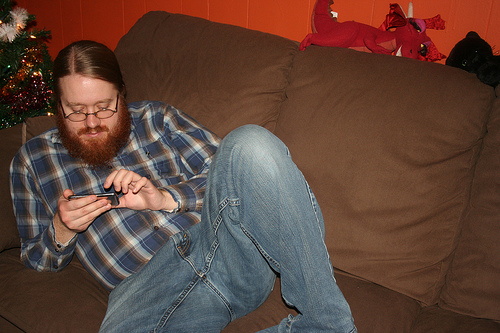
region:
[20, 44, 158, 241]
A man looking at a cell phone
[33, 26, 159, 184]
A man wearing glasses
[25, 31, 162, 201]
A man with a beard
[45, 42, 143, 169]
A man with a mustache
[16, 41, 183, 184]
A man with a beard and a mustache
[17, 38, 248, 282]
A man wearing a plaid shirt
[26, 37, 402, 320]
A man wearing blue jeans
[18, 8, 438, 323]
A man lounging on a sofa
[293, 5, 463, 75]
A stuffed red dinosaur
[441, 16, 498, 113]
A stuffed black cat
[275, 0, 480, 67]
stuffed red dragon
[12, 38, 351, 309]
man using his cellphone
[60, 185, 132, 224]
thin grey cellphone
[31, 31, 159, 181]
man with a thick orange beard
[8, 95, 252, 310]
blue white and orange checkered shirt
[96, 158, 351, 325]
faded blue jeans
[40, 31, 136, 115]
orange hair that is slicked down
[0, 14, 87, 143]
christmas tree with decorations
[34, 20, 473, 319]
man sitting on a brown couch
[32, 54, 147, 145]
man wearing glasses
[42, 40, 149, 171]
Male wearing glasses with a large red beard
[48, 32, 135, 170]
Slicked red hair on a male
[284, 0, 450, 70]
Red stuffed dragon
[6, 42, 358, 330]
Man laying on couch looking at phone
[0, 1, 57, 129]
Decorated Christmas tree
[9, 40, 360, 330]
Guy wearing plaid decorate button down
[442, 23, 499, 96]
Stuffed black bear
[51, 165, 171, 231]
Hands manipulating phone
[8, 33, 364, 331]
Man relaxing in jeans using cellphone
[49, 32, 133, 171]
Caucasian guy with a red beard and mustache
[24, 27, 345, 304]
man on couch playing with cell phone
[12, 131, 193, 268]
man wearing blue and beige plaid shirt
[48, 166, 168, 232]
man typing message on cell phone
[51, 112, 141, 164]
man has red beard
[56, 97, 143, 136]
man with glasses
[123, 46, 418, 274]
man resting on brown couch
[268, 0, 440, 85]
colorful stuffed animal toy on back of couch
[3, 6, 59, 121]
Christmas ornaments behind the man's head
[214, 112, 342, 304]
man wearing worn blue jeans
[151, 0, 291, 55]
walll behind the couch appears to be orange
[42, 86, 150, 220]
Man is looking at his phone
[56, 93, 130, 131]
Man is wearing eyeglasses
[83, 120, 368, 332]
Man is wearing jeans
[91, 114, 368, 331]
Man's jeans are blue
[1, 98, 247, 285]
Man is wearing a plaid shirt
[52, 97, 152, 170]
Man has a long beard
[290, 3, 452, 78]
A stuffed animal in the background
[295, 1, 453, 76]
Stuffed animal is red in color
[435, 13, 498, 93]
A black stuffed animal in the background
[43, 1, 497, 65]
The background wall is orange in color